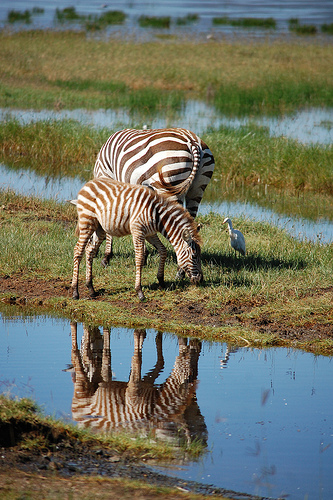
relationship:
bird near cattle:
[222, 217, 246, 264] [71, 125, 216, 301]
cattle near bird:
[71, 125, 216, 301] [222, 217, 246, 264]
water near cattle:
[5, 290, 332, 496] [71, 125, 216, 301]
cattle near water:
[71, 125, 216, 301] [5, 290, 332, 496]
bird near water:
[222, 217, 246, 264] [5, 290, 332, 496]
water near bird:
[5, 290, 332, 496] [222, 217, 246, 264]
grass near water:
[8, 21, 332, 344] [5, 290, 332, 496]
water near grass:
[5, 290, 332, 496] [8, 21, 332, 344]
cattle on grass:
[71, 125, 216, 301] [8, 21, 332, 344]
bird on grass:
[222, 217, 246, 264] [8, 21, 332, 344]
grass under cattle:
[8, 21, 332, 344] [71, 125, 216, 301]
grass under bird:
[8, 21, 332, 344] [222, 217, 246, 264]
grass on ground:
[0, 1, 333, 499] [5, 39, 316, 493]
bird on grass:
[220, 211, 253, 264] [3, 27, 322, 258]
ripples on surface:
[13, 323, 184, 385] [21, 96, 313, 138]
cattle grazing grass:
[71, 125, 216, 301] [4, 5, 307, 355]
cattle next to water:
[71, 125, 216, 301] [6, 313, 300, 486]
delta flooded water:
[9, 93, 314, 422] [10, 307, 307, 473]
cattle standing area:
[71, 125, 215, 313] [5, 96, 322, 419]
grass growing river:
[8, 21, 332, 344] [2, 311, 315, 492]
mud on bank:
[14, 275, 40, 296] [9, 274, 303, 352]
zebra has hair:
[68, 172, 215, 299] [155, 182, 205, 250]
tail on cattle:
[151, 141, 201, 197] [71, 125, 216, 301]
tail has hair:
[151, 141, 201, 197] [155, 182, 204, 242]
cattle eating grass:
[71, 125, 216, 301] [3, 191, 319, 328]